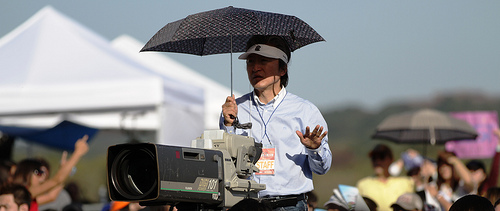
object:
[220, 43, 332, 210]
person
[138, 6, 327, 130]
umbrella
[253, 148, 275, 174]
tag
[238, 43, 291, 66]
visor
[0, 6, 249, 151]
tent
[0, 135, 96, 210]
people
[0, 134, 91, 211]
woman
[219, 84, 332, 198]
shirt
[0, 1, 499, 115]
sky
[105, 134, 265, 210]
camera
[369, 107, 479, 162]
umbrella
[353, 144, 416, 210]
person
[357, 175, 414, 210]
shirt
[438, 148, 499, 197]
person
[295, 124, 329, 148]
hand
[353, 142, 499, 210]
crowd